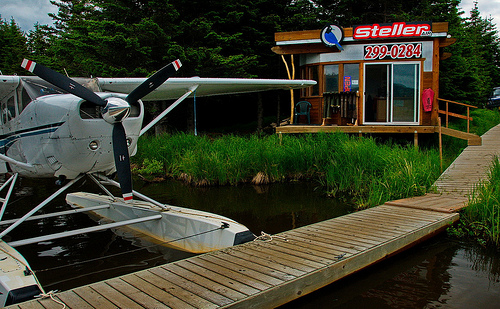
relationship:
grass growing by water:
[140, 129, 447, 206] [198, 190, 349, 219]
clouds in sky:
[0, 0, 59, 30] [0, 0, 55, 32]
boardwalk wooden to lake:
[2, 122, 498, 307] [2, 177, 497, 307]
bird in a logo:
[323, 24, 353, 61] [318, 20, 343, 52]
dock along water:
[1, 121, 498, 307] [2, 172, 497, 305]